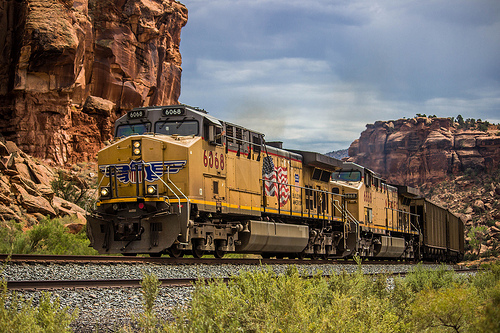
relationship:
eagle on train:
[98, 158, 184, 185] [86, 97, 466, 266]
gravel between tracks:
[118, 263, 249, 275] [26, 240, 264, 294]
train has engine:
[88, 90, 474, 302] [122, 102, 243, 240]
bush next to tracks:
[3, 264, 498, 331] [0, 249, 499, 285]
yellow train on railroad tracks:
[132, 108, 409, 240] [24, 247, 126, 285]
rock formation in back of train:
[339, 115, 498, 257] [86, 97, 466, 266]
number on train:
[202, 147, 227, 170] [86, 97, 466, 266]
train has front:
[86, 97, 466, 266] [98, 103, 200, 238]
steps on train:
[327, 199, 362, 261] [86, 97, 466, 266]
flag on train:
[259, 159, 307, 209] [86, 97, 466, 266]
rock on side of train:
[7, 3, 201, 245] [86, 97, 466, 266]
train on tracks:
[88, 90, 474, 302] [2, 252, 482, 290]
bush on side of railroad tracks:
[3, 264, 499, 332] [1, 243, 498, 300]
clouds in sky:
[209, 6, 294, 36] [171, 0, 498, 150]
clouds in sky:
[209, 6, 294, 36] [178, 3, 499, 163]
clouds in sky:
[209, 6, 294, 36] [213, 16, 378, 132]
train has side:
[88, 90, 474, 302] [275, 169, 387, 218]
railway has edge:
[65, 239, 100, 266] [44, 271, 84, 296]